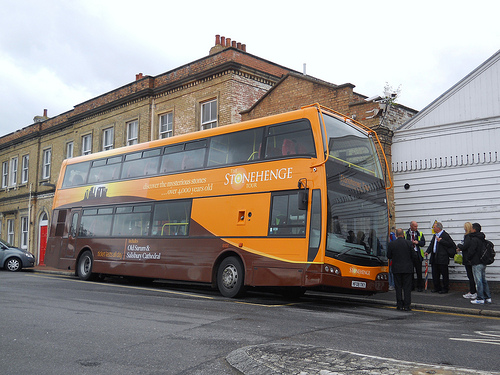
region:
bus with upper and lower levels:
[38, 99, 384, 299]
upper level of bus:
[67, 152, 322, 189]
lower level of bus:
[50, 206, 385, 283]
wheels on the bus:
[57, 251, 257, 301]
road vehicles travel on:
[7, 277, 204, 342]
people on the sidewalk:
[411, 218, 490, 298]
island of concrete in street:
[182, 332, 334, 374]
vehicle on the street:
[0, 233, 39, 278]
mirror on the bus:
[290, 164, 313, 216]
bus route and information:
[340, 168, 384, 200]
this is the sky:
[25, 13, 64, 56]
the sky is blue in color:
[35, 22, 72, 57]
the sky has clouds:
[44, 16, 108, 69]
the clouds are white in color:
[161, 24, 193, 51]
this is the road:
[65, 292, 135, 371]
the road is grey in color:
[61, 312, 148, 374]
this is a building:
[4, 134, 48, 230]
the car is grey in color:
[11, 250, 20, 255]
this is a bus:
[37, 107, 394, 297]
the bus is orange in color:
[203, 199, 221, 219]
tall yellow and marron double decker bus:
[23, 104, 395, 278]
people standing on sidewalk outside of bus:
[380, 204, 495, 316]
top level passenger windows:
[63, 119, 320, 197]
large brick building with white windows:
[8, 46, 273, 254]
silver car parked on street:
[0, 233, 44, 277]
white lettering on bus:
[147, 159, 299, 204]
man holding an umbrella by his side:
[418, 212, 460, 297]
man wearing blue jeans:
[460, 216, 495, 304]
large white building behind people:
[386, 65, 498, 287]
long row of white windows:
[7, 99, 220, 196]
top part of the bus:
[41, 125, 338, 180]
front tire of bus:
[218, 245, 268, 320]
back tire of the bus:
[61, 219, 117, 306]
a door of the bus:
[283, 173, 338, 274]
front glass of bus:
[311, 163, 400, 265]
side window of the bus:
[45, 178, 204, 243]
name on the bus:
[221, 155, 298, 190]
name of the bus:
[84, 223, 183, 278]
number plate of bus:
[335, 260, 376, 310]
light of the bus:
[323, 262, 352, 279]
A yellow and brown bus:
[44, 104, 391, 297]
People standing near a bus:
[387, 222, 494, 317]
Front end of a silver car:
[0, 238, 35, 272]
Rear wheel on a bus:
[75, 247, 94, 281]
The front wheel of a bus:
[211, 253, 246, 300]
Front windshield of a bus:
[323, 187, 392, 269]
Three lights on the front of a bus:
[321, 262, 341, 277]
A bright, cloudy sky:
[1, 2, 498, 115]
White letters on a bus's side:
[221, 170, 298, 182]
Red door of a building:
[39, 223, 50, 267]